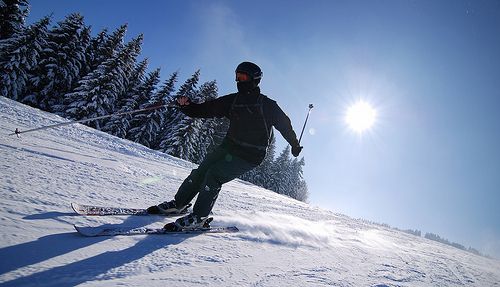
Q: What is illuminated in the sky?
A: Sun.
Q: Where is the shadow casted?
A: Snow.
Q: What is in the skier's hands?
A: Ski poles.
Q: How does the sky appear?
A: Blue and clear.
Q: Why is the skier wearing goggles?
A: Protect eyes.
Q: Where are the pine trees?
A: Edge of hill.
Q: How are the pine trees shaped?
A: Triangles.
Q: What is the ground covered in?
A: Snow.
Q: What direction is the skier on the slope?
A: Down to the left.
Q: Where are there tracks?
A: In snow.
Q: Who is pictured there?
A: Skier.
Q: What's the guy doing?
A: Skiing.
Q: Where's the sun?
A: Background.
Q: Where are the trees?
A: Right of man.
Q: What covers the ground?
A: Snow.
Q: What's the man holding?
A: Poles.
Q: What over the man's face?
A: Ski mask.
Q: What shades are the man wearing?
A: Dark.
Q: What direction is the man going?
A: Southwest.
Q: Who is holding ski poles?
A: Skier.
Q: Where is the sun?
A: In the sky.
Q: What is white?
A: Snow.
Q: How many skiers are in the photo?
A: One.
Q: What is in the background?
A: Trees.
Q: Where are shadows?
A: On the snow.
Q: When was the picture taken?
A: Daytime.